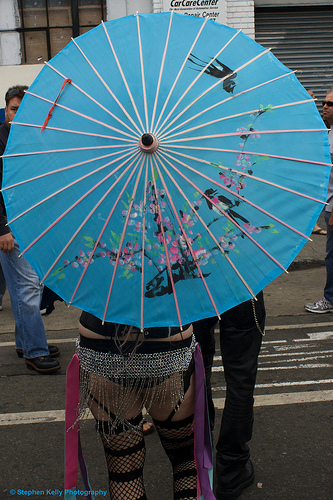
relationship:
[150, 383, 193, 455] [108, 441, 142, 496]
back of leg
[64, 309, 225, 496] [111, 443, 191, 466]
woman wearing fishnet stockings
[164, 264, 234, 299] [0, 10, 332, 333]
part of an umbrella